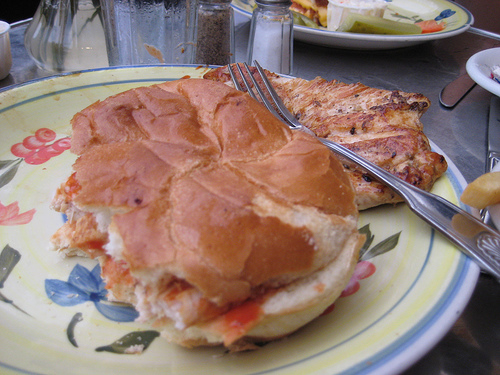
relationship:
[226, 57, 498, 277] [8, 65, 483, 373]
fork on plate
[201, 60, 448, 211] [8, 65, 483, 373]
chicken on plate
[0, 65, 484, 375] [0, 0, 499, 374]
plate on table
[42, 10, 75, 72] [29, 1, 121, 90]
stem in vase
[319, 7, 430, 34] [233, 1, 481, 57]
pickle on plate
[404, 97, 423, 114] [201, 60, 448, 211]
browned bit on chicken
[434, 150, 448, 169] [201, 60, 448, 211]
browned bit on chicken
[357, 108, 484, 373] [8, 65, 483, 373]
edging on plate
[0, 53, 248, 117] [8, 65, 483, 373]
edging on plate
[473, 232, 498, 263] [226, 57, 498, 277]
logo on fork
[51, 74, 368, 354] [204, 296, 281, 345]
sandwich has sauce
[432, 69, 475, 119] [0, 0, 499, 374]
knife on table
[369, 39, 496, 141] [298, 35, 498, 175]
table has edge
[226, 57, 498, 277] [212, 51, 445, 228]
fork on chicken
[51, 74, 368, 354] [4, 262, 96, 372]
sandwich on plate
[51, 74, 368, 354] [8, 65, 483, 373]
sandwich on plate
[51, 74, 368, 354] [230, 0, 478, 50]
sandwich on plate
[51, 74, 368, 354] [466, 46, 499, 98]
sandwich on plate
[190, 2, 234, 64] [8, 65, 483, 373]
pepper shaker behind plate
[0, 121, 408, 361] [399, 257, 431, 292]
pattern on plate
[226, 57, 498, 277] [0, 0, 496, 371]
fork from a restaurant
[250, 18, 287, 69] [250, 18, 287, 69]
salt in salt